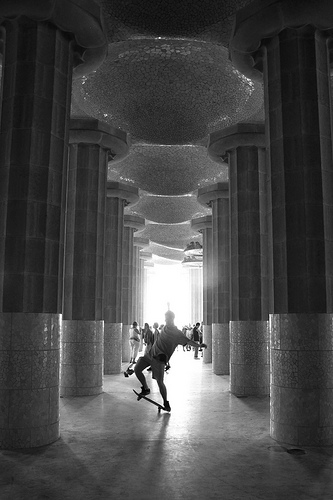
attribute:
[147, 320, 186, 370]
shirt — black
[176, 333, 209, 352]
arm — stretched out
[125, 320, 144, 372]
woman — standing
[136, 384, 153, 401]
shoe — black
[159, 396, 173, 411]
shoe — black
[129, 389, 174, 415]
skateboard — raised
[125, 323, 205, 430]
light — reflecting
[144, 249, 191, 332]
outdoor — sunny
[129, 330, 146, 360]
cloths — white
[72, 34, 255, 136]
design — concave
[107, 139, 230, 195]
design — concave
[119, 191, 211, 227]
design — concave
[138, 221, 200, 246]
design — concave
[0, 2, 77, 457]
column — painted, white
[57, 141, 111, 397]
column — painted, white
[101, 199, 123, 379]
column — painted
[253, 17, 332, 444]
column — painted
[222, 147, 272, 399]
column — painted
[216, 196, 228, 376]
column — painted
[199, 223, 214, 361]
column — painted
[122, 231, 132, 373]
column — painted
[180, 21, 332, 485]
columns —  cement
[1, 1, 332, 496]
building —  stone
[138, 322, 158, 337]
people —  in background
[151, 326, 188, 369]
shirt — black 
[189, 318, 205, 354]
woman —  in black,  in background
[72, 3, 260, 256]
ceiling — concave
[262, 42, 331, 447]
poles — brick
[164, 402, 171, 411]
shoe — black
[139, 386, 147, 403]
shoe — black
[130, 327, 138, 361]
outfit —  white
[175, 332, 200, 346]
arms — extended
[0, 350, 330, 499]
hallway — grey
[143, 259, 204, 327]
light —  in background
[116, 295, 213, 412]
people —  in background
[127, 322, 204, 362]
people — grouped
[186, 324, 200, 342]
people — many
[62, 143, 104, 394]
pole — round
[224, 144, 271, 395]
pole — round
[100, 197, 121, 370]
pole — round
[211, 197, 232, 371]
pole — round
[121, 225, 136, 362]
pole — round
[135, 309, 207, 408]
man — skating